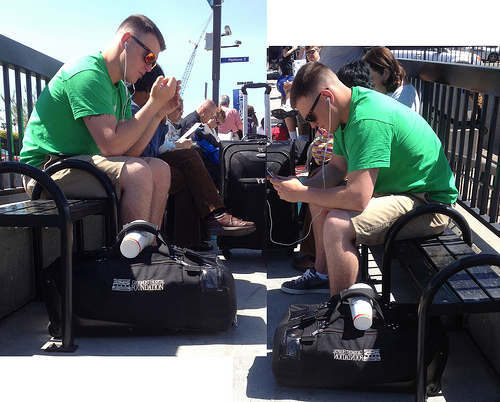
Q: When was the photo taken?
A: Daytime.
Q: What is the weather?
A: Sunny.